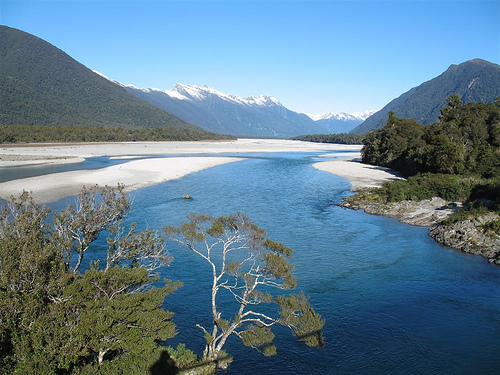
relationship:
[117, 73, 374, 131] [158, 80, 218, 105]
peaks covered in snow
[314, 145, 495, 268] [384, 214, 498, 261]
line covered with rocks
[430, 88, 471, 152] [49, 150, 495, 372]
tree by river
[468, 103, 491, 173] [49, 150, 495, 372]
tree by river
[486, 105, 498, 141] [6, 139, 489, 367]
tree by river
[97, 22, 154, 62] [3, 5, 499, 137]
clouds in sky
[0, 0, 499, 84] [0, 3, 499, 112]
clouds in sky